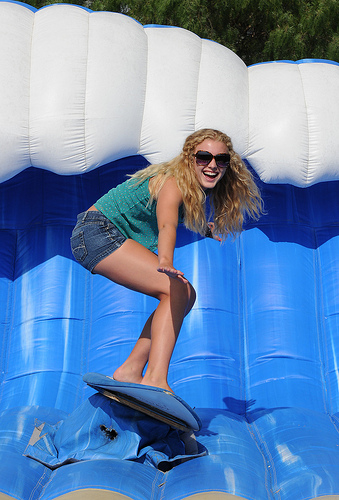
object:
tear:
[99, 423, 119, 440]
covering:
[2, 184, 338, 499]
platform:
[59, 355, 245, 483]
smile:
[201, 166, 220, 182]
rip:
[99, 425, 117, 441]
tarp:
[0, 1, 337, 496]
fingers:
[156, 263, 188, 285]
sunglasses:
[192, 149, 230, 168]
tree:
[299, 5, 332, 56]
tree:
[266, 9, 300, 56]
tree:
[175, 1, 214, 38]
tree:
[122, 1, 149, 23]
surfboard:
[82, 373, 202, 433]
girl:
[70, 129, 268, 397]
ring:
[208, 225, 215, 234]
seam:
[74, 22, 95, 164]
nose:
[208, 158, 218, 170]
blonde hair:
[126, 128, 269, 247]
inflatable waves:
[1, 1, 335, 496]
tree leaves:
[90, 0, 336, 61]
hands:
[157, 221, 222, 285]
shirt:
[94, 169, 161, 253]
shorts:
[70, 210, 126, 274]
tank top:
[93, 170, 157, 253]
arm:
[156, 185, 188, 262]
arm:
[174, 220, 212, 248]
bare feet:
[112, 357, 178, 396]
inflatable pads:
[259, 212, 323, 297]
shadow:
[189, 396, 293, 436]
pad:
[4, 17, 336, 498]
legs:
[87, 236, 196, 394]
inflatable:
[0, 2, 338, 496]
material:
[2, 33, 323, 159]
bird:
[222, 396, 256, 415]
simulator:
[21, 369, 208, 463]